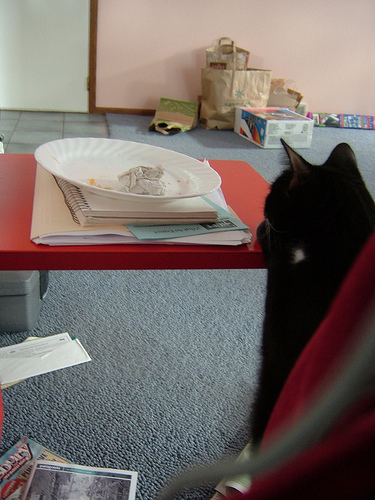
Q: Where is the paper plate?
A: On the notebook.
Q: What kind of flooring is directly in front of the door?
A: Tile.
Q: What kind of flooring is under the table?
A: Carpet.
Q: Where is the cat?
A: Sitting in the chair.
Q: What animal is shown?
A: Cat.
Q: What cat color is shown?
A: Black.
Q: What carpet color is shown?
A: Beige.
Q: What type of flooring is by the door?
A: Tile.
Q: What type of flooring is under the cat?
A: Carpet.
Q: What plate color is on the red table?
A: White.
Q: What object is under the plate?
A: Notebook.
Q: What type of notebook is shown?
A: Spiral bound.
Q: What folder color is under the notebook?
A: Manilla.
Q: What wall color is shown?
A: Pink.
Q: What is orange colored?
A: Tablecloth.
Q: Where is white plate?
A: On table.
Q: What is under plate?
A: Magazines.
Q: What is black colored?
A: Cat.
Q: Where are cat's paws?
A: On table.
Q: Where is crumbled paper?
A: On plate.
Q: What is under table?
A: Carpet.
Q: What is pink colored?
A: Wall.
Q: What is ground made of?
A: Blue carpet.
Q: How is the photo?
A: Blurry.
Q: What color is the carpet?
A: Grey.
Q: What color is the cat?
A: Black.